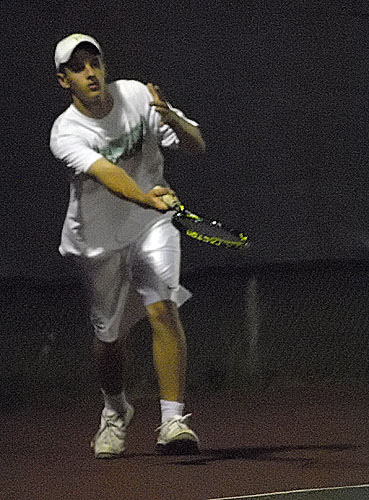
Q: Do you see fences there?
A: Yes, there is a fence.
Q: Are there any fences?
A: Yes, there is a fence.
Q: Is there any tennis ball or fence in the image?
A: Yes, there is a fence.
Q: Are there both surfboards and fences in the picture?
A: No, there is a fence but no surfboards.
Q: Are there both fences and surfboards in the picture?
A: No, there is a fence but no surfboards.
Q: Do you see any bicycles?
A: No, there are no bicycles.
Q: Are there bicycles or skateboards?
A: No, there are no bicycles or skateboards.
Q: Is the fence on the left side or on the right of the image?
A: The fence is on the right of the image.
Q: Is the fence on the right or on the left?
A: The fence is on the right of the image.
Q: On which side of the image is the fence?
A: The fence is on the right of the image.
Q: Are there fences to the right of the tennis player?
A: Yes, there is a fence to the right of the player.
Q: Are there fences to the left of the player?
A: No, the fence is to the right of the player.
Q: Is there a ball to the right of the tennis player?
A: No, there is a fence to the right of the player.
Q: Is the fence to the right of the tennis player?
A: Yes, the fence is to the right of the player.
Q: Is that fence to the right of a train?
A: No, the fence is to the right of the player.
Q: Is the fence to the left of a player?
A: No, the fence is to the right of a player.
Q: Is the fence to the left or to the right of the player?
A: The fence is to the right of the player.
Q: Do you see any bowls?
A: No, there are no bowls.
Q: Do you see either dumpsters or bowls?
A: No, there are no bowls or dumpsters.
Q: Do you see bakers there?
A: No, there are no bakers.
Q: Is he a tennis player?
A: Yes, this is a tennis player.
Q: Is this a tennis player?
A: Yes, this is a tennis player.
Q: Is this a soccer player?
A: No, this is a tennis player.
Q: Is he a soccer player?
A: No, this is a tennis player.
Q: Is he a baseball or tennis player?
A: This is a tennis player.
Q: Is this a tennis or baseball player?
A: This is a tennis player.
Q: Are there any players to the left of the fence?
A: Yes, there is a player to the left of the fence.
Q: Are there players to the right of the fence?
A: No, the player is to the left of the fence.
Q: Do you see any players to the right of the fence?
A: No, the player is to the left of the fence.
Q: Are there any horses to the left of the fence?
A: No, there is a player to the left of the fence.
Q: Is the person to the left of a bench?
A: No, the player is to the left of the fence.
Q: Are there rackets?
A: Yes, there is a racket.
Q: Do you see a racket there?
A: Yes, there is a racket.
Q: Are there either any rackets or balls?
A: Yes, there is a racket.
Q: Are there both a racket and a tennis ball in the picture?
A: No, there is a racket but no tennis balls.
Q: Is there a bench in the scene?
A: No, there are no benches.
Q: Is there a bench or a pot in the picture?
A: No, there are no benches or pots.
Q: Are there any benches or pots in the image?
A: No, there are no benches or pots.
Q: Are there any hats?
A: Yes, there is a hat.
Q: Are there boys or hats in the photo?
A: Yes, there is a hat.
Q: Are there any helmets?
A: No, there are no helmets.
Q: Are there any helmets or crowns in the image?
A: No, there are no helmets or crowns.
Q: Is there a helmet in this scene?
A: No, there are no helmets.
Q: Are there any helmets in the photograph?
A: No, there are no helmets.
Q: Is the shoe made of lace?
A: Yes, the shoe is made of lace.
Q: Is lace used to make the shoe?
A: Yes, the shoe is made of lace.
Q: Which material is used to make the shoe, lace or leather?
A: The shoe is made of lace.